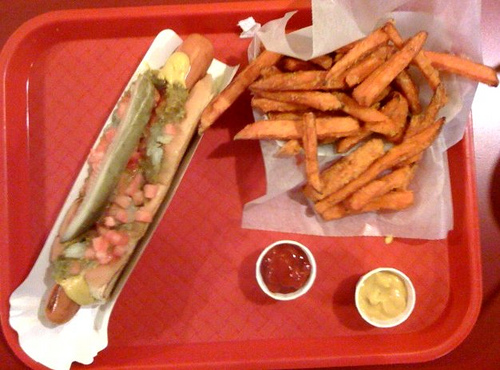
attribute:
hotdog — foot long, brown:
[58, 34, 220, 360]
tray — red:
[2, 11, 499, 369]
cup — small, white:
[253, 228, 318, 303]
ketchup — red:
[273, 253, 299, 281]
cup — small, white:
[353, 261, 416, 334]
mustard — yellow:
[375, 283, 396, 321]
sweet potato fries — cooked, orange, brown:
[237, 29, 442, 143]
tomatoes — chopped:
[101, 206, 139, 252]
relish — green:
[165, 89, 187, 120]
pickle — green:
[57, 81, 156, 241]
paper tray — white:
[236, 20, 458, 225]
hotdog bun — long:
[85, 80, 219, 300]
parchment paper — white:
[307, 1, 483, 151]